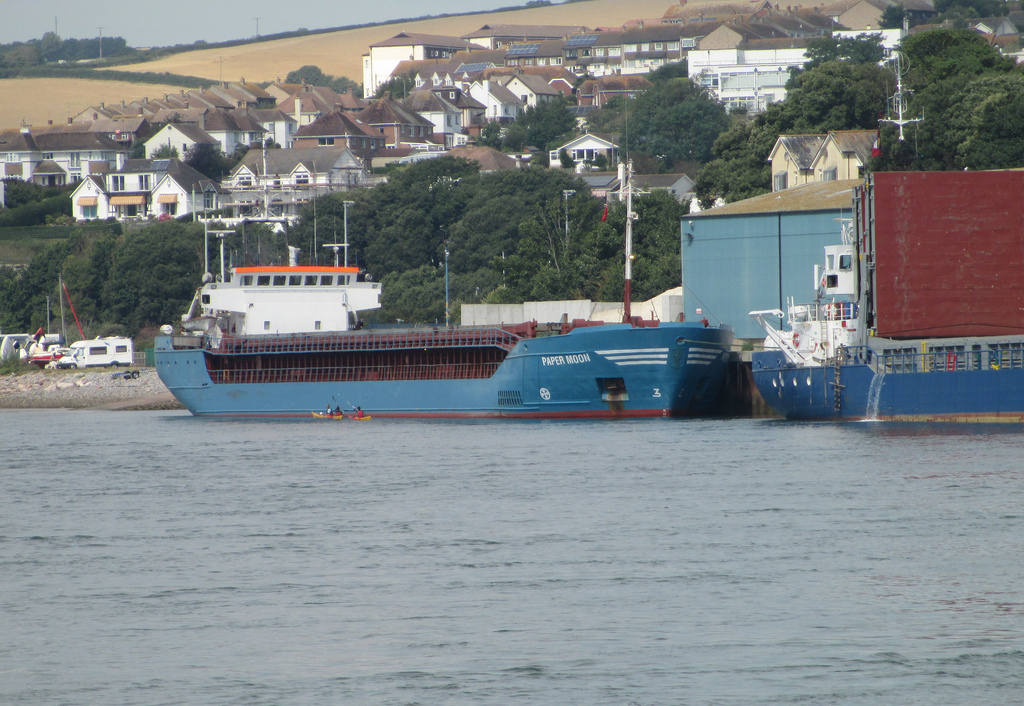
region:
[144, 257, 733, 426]
A boat in the water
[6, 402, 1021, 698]
Water in a harbor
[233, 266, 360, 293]
Windows on a boat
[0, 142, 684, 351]
Green trees near the water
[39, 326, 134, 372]
A camper near the water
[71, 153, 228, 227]
A house near the trees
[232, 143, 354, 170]
A roof on a house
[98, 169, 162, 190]
Windows on a house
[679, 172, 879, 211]
A roof on a building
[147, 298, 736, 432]
blue boat in the water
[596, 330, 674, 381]
three white stripes on the boat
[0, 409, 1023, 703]
pretty calm body of water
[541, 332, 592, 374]
white writing on the side of the boat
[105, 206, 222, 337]
thick dark green tree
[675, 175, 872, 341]
blue building with a tan roof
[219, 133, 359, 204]
white building with a gray roof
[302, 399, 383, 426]
kayakers in the water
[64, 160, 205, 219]
white house on the hill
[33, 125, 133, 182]
white house on the hill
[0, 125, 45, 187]
white house on the hill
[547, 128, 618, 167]
white house on the hill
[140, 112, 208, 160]
white house on the hill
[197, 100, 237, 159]
white house on the hill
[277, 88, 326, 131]
white house on the hill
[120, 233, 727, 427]
Large ship in the dock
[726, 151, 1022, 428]
Large ship in the dock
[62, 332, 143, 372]
RV parked in the trailer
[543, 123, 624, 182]
house on the hill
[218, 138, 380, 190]
house on the hill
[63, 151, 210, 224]
house on the hill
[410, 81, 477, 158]
house on the hill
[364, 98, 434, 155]
house on the hill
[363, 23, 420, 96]
house on the hill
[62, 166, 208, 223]
house on the hill by the water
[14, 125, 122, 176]
house on the hill by the water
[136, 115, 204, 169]
house on the hill by the water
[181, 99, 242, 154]
house on the hill by the water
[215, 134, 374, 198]
house on the hill by the water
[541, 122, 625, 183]
house on the hill by the water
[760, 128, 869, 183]
house on the hill by the water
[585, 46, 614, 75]
house on the hill by the water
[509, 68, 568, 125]
house on the hill by the water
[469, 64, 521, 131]
house on the hill by the water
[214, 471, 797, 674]
water next to boat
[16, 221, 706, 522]
boat in the water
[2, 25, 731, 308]
houses next to water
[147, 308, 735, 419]
a large blue ship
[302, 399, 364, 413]
a small boat in the water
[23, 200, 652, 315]
trees behind the ship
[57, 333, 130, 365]
a white van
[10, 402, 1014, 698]
a large body of water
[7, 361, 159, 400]
rocks next to the water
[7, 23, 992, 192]
houses on the hill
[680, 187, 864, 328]
a large blue building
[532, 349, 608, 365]
writing on the ship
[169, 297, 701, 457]
large blue and white boat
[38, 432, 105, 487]
ripples in gray colored water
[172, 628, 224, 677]
ripples in gray colored water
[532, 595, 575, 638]
ripples in gray colored water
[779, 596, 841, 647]
ripples in gray colored water